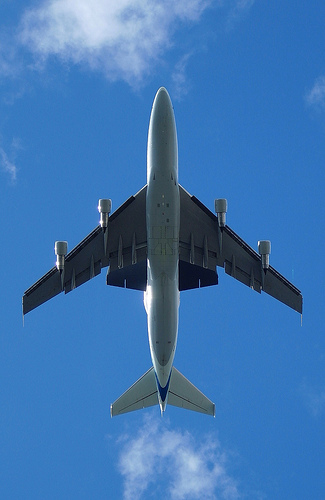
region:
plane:
[32, 73, 297, 431]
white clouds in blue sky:
[15, 420, 55, 457]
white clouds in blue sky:
[85, 444, 151, 479]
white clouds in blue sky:
[164, 415, 211, 451]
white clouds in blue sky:
[201, 427, 238, 459]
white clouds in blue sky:
[221, 354, 276, 399]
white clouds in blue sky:
[0, 355, 64, 401]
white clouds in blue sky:
[233, 130, 272, 179]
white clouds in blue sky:
[51, 116, 77, 155]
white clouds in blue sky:
[62, 1, 135, 58]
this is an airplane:
[154, 226, 179, 285]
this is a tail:
[109, 313, 225, 457]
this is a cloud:
[113, 410, 217, 492]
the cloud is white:
[99, 327, 192, 496]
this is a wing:
[80, 240, 116, 275]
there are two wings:
[58, 234, 232, 414]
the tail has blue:
[121, 315, 175, 429]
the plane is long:
[106, 260, 286, 490]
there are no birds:
[86, 326, 114, 477]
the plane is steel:
[101, 346, 159, 385]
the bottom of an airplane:
[21, 83, 306, 424]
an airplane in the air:
[20, 77, 306, 417]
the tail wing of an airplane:
[109, 369, 155, 419]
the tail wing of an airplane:
[171, 363, 216, 417]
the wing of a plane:
[179, 183, 304, 313]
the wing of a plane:
[18, 182, 147, 315]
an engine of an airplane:
[52, 238, 69, 291]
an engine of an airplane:
[95, 195, 112, 247]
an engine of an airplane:
[211, 195, 230, 248]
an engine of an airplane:
[255, 236, 272, 287]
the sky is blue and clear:
[217, 8, 311, 204]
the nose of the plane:
[148, 79, 172, 94]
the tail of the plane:
[93, 345, 227, 418]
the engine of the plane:
[91, 187, 107, 226]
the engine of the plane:
[195, 195, 226, 221]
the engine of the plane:
[256, 237, 276, 263]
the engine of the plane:
[40, 234, 66, 273]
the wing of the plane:
[13, 172, 137, 315]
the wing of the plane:
[183, 182, 311, 322]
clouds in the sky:
[32, 4, 168, 74]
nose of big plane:
[147, 86, 175, 99]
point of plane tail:
[153, 403, 171, 417]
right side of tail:
[185, 384, 226, 420]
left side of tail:
[102, 386, 133, 425]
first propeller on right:
[251, 232, 275, 279]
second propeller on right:
[203, 191, 235, 234]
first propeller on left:
[41, 234, 74, 274]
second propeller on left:
[87, 195, 116, 228]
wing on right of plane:
[286, 275, 308, 320]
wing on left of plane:
[17, 286, 42, 318]